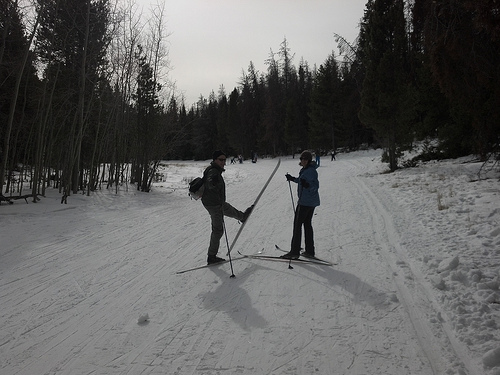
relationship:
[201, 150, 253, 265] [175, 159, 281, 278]
person wearing equipment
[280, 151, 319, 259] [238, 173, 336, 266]
person wearing equipment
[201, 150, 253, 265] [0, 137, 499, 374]
person on snow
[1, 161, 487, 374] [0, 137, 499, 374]
path has snow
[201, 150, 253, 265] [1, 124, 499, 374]
person on top of hill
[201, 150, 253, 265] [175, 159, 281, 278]
person wearing skis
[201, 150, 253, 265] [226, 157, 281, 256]
person kicking ski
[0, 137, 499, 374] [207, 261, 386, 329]
snow has shadows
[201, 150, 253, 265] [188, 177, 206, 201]
person has a backpack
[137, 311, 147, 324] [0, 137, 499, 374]
ice on top of snow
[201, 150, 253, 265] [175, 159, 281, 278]
person has skis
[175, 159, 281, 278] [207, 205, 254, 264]
skis on feet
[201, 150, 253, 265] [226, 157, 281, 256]
person holding ski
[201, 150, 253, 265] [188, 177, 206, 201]
person has backpack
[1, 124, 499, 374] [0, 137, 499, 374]
hill has snow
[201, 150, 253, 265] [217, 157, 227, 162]
person wearing sunglasses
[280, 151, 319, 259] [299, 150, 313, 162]
person wearing hat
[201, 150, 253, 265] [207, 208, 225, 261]
person has a leg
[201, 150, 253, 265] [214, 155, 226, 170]
person has a face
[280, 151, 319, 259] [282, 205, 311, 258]
person has a leg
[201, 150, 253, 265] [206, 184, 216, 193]
person has a elbow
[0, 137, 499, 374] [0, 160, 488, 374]
snow has marks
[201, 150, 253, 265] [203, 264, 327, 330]
person has shadow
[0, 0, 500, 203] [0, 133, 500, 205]
trees have bottom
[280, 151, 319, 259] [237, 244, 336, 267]
person has skis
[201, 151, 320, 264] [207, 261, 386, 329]
couple has shadows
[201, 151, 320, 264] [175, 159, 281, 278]
couple enjoying skis